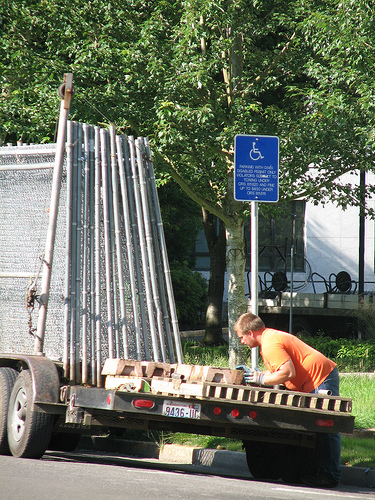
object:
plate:
[161, 394, 205, 420]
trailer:
[0, 339, 355, 488]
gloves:
[241, 366, 263, 388]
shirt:
[257, 323, 336, 395]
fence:
[0, 117, 74, 382]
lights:
[129, 397, 159, 415]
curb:
[156, 440, 247, 464]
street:
[8, 447, 251, 499]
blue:
[238, 139, 247, 151]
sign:
[232, 132, 281, 203]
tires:
[7, 361, 56, 461]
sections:
[1, 155, 64, 356]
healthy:
[94, 27, 112, 43]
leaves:
[290, 17, 355, 70]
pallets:
[104, 356, 241, 401]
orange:
[297, 355, 316, 371]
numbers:
[164, 406, 171, 416]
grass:
[345, 375, 370, 396]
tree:
[158, 0, 250, 371]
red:
[106, 361, 117, 373]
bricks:
[100, 358, 144, 378]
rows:
[71, 120, 78, 380]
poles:
[79, 115, 89, 389]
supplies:
[0, 119, 200, 387]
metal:
[67, 163, 89, 192]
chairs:
[327, 269, 358, 295]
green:
[311, 18, 336, 32]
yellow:
[143, 362, 154, 377]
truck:
[0, 344, 351, 486]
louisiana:
[168, 400, 188, 408]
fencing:
[2, 116, 79, 382]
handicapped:
[246, 139, 264, 163]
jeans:
[321, 368, 339, 393]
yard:
[201, 337, 369, 365]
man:
[232, 308, 338, 398]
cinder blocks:
[100, 357, 250, 388]